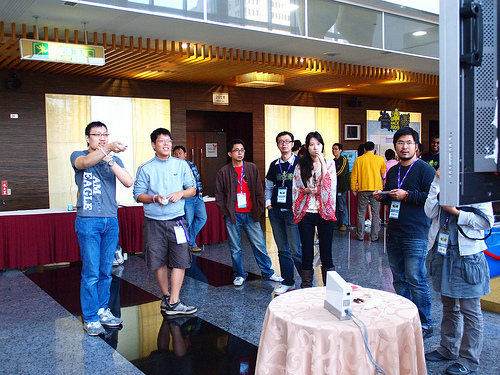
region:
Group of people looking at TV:
[62, 103, 497, 352]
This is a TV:
[437, 3, 499, 230]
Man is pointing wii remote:
[107, 138, 136, 165]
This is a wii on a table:
[317, 263, 362, 327]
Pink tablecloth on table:
[255, 271, 422, 373]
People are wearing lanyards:
[227, 158, 439, 213]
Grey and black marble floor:
[1, 218, 477, 373]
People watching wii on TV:
[80, 109, 463, 179]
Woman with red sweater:
[286, 130, 345, 231]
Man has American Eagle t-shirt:
[73, 156, 123, 223]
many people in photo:
[40, 86, 445, 228]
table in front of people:
[277, 256, 422, 368]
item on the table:
[296, 265, 362, 331]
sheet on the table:
[223, 277, 329, 373]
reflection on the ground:
[113, 302, 163, 361]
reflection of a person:
[117, 323, 203, 373]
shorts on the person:
[134, 212, 203, 278]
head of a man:
[383, 128, 427, 167]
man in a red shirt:
[215, 118, 272, 208]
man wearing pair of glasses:
[263, 128, 303, 167]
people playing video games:
[73, 120, 442, 257]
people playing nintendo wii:
[54, 108, 434, 253]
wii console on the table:
[314, 260, 375, 335]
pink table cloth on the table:
[262, 285, 437, 374]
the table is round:
[250, 284, 435, 367]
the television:
[422, 3, 499, 204]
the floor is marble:
[13, 275, 75, 374]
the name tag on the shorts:
[161, 217, 192, 248]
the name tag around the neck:
[225, 187, 257, 213]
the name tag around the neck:
[270, 154, 301, 208]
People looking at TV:
[52, 106, 465, 188]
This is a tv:
[432, 0, 497, 235]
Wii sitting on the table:
[315, 262, 377, 337]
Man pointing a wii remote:
[102, 139, 140, 161]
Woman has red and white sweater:
[287, 147, 357, 232]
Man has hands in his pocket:
[205, 151, 282, 235]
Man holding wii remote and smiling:
[137, 126, 198, 213]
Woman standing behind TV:
[425, 168, 492, 318]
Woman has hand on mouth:
[297, 126, 329, 173]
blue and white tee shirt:
[71, 150, 126, 217]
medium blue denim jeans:
[76, 214, 121, 321]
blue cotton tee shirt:
[133, 159, 198, 219]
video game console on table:
[325, 270, 352, 321]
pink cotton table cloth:
[258, 286, 428, 373]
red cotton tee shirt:
[233, 163, 253, 214]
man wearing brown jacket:
[215, 140, 282, 284]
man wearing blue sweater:
[381, 130, 434, 337]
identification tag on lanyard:
[436, 232, 450, 259]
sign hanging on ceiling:
[21, 38, 106, 65]